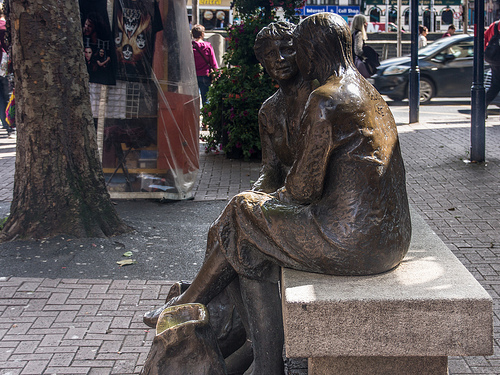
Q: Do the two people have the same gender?
A: No, they are both male and female.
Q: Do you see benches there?
A: Yes, there is a bench.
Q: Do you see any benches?
A: Yes, there is a bench.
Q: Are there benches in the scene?
A: Yes, there is a bench.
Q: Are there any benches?
A: Yes, there is a bench.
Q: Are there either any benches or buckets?
A: Yes, there is a bench.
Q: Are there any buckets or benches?
A: Yes, there is a bench.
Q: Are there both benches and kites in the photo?
A: No, there is a bench but no kites.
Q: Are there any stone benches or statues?
A: Yes, there is a stone bench.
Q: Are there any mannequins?
A: No, there are no mannequins.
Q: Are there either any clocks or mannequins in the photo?
A: No, there are no mannequins or clocks.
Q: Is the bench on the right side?
A: Yes, the bench is on the right of the image.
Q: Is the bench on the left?
A: No, the bench is on the right of the image.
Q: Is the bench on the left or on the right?
A: The bench is on the right of the image.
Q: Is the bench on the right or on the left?
A: The bench is on the right of the image.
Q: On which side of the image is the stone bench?
A: The bench is on the right of the image.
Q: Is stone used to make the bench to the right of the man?
A: Yes, the bench is made of stone.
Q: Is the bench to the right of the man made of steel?
A: No, the bench is made of stone.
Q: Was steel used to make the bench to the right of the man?
A: No, the bench is made of stone.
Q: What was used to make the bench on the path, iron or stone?
A: The bench is made of stone.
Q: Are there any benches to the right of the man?
A: Yes, there is a bench to the right of the man.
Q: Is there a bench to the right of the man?
A: Yes, there is a bench to the right of the man.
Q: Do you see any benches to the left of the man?
A: No, the bench is to the right of the man.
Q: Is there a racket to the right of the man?
A: No, there is a bench to the right of the man.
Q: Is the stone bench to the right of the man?
A: Yes, the bench is to the right of the man.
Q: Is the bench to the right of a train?
A: No, the bench is to the right of the man.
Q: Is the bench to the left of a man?
A: No, the bench is to the right of a man.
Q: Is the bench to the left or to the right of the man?
A: The bench is to the right of the man.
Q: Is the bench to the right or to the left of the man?
A: The bench is to the right of the man.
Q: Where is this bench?
A: The bench is on the path.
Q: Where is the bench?
A: The bench is on the path.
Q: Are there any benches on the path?
A: Yes, there is a bench on the path.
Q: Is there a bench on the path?
A: Yes, there is a bench on the path.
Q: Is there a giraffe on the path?
A: No, there is a bench on the path.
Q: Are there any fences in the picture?
A: No, there are no fences.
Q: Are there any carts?
A: No, there are no carts.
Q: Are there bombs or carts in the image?
A: No, there are no carts or bombs.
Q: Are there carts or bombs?
A: No, there are no carts or bombs.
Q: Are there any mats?
A: No, there are no mats.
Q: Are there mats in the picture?
A: No, there are no mats.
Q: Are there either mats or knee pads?
A: No, there are no mats or knee pads.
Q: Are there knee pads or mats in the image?
A: No, there are no mats or knee pads.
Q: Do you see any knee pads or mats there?
A: No, there are no mats or knee pads.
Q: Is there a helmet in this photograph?
A: No, there are no helmets.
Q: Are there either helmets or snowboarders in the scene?
A: No, there are no helmets or snowboarders.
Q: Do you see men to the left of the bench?
A: Yes, there is a man to the left of the bench.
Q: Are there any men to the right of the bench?
A: No, the man is to the left of the bench.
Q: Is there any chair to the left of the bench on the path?
A: No, there is a man to the left of the bench.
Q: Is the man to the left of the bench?
A: Yes, the man is to the left of the bench.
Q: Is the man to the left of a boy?
A: No, the man is to the left of the bench.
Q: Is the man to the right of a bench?
A: No, the man is to the left of a bench.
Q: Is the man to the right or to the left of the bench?
A: The man is to the left of the bench.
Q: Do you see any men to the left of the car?
A: Yes, there is a man to the left of the car.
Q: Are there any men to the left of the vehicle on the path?
A: Yes, there is a man to the left of the car.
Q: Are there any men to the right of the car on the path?
A: No, the man is to the left of the car.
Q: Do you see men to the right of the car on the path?
A: No, the man is to the left of the car.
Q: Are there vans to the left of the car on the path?
A: No, there is a man to the left of the car.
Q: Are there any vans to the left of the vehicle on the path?
A: No, there is a man to the left of the car.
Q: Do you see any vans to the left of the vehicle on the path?
A: No, there is a man to the left of the car.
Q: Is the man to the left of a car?
A: Yes, the man is to the left of a car.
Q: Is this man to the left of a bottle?
A: No, the man is to the left of a car.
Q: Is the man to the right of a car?
A: No, the man is to the left of a car.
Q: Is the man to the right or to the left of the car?
A: The man is to the left of the car.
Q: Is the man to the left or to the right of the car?
A: The man is to the left of the car.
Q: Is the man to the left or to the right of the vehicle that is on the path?
A: The man is to the left of the car.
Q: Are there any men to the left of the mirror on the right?
A: Yes, there is a man to the left of the mirror.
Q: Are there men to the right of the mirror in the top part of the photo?
A: No, the man is to the left of the mirror.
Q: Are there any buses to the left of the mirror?
A: No, there is a man to the left of the mirror.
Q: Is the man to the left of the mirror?
A: Yes, the man is to the left of the mirror.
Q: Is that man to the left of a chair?
A: No, the man is to the left of the mirror.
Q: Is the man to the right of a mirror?
A: No, the man is to the left of a mirror.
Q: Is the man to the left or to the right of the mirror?
A: The man is to the left of the mirror.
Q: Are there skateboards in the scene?
A: No, there are no skateboards.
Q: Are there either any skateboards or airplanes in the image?
A: No, there are no skateboards or airplanes.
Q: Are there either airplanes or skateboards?
A: No, there are no skateboards or airplanes.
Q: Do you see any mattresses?
A: No, there are no mattresses.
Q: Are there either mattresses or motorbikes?
A: No, there are no mattresses or motorbikes.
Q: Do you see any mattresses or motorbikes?
A: No, there are no mattresses or motorbikes.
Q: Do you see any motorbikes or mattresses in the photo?
A: No, there are no mattresses or motorbikes.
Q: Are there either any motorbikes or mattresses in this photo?
A: No, there are no mattresses or motorbikes.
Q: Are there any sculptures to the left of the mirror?
A: Yes, there is a sculpture to the left of the mirror.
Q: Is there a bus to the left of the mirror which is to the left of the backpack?
A: No, there is a sculpture to the left of the mirror.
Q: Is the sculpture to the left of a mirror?
A: Yes, the sculpture is to the left of a mirror.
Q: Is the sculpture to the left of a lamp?
A: No, the sculpture is to the left of a mirror.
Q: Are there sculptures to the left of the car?
A: Yes, there is a sculpture to the left of the car.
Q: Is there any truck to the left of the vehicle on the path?
A: No, there is a sculpture to the left of the car.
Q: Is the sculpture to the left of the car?
A: Yes, the sculpture is to the left of the car.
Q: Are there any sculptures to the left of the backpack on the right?
A: Yes, there is a sculpture to the left of the backpack.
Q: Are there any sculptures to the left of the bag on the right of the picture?
A: Yes, there is a sculpture to the left of the backpack.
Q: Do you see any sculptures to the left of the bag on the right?
A: Yes, there is a sculpture to the left of the backpack.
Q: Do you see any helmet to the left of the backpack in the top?
A: No, there is a sculpture to the left of the backpack.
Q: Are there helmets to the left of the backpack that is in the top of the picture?
A: No, there is a sculpture to the left of the backpack.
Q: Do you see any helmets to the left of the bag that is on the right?
A: No, there is a sculpture to the left of the backpack.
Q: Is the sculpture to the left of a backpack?
A: Yes, the sculpture is to the left of a backpack.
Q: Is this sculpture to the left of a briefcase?
A: No, the sculpture is to the left of a backpack.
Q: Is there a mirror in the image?
A: Yes, there is a mirror.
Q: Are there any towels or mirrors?
A: Yes, there is a mirror.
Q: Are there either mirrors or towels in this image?
A: Yes, there is a mirror.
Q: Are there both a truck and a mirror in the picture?
A: No, there is a mirror but no trucks.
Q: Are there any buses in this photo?
A: No, there are no buses.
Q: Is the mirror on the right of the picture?
A: Yes, the mirror is on the right of the image.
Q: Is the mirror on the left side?
A: No, the mirror is on the right of the image.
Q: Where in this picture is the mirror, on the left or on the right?
A: The mirror is on the right of the image.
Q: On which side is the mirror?
A: The mirror is on the right of the image.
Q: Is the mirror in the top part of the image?
A: Yes, the mirror is in the top of the image.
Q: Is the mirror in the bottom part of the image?
A: No, the mirror is in the top of the image.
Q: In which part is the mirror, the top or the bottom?
A: The mirror is in the top of the image.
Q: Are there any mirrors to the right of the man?
A: Yes, there is a mirror to the right of the man.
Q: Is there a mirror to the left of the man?
A: No, the mirror is to the right of the man.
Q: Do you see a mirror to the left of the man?
A: No, the mirror is to the right of the man.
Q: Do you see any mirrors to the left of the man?
A: No, the mirror is to the right of the man.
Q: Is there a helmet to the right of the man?
A: No, there is a mirror to the right of the man.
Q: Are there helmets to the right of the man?
A: No, there is a mirror to the right of the man.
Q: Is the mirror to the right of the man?
A: Yes, the mirror is to the right of the man.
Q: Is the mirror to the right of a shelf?
A: No, the mirror is to the right of the man.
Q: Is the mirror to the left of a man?
A: No, the mirror is to the right of a man.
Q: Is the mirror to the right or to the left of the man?
A: The mirror is to the right of the man.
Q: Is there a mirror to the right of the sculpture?
A: Yes, there is a mirror to the right of the sculpture.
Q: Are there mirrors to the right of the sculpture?
A: Yes, there is a mirror to the right of the sculpture.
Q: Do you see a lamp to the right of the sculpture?
A: No, there is a mirror to the right of the sculpture.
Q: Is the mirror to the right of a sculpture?
A: Yes, the mirror is to the right of a sculpture.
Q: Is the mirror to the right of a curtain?
A: No, the mirror is to the right of a sculpture.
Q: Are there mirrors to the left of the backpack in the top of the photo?
A: Yes, there is a mirror to the left of the backpack.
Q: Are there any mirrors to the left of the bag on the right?
A: Yes, there is a mirror to the left of the backpack.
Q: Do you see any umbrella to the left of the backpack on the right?
A: No, there is a mirror to the left of the backpack.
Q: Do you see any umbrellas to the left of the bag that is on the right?
A: No, there is a mirror to the left of the backpack.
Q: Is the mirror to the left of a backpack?
A: Yes, the mirror is to the left of a backpack.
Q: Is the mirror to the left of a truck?
A: No, the mirror is to the left of a backpack.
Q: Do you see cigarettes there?
A: No, there are no cigarettes.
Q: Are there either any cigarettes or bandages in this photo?
A: No, there are no cigarettes or bandages.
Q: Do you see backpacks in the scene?
A: Yes, there is a backpack.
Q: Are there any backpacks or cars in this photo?
A: Yes, there is a backpack.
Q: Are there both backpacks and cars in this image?
A: Yes, there are both a backpack and a car.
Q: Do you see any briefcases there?
A: No, there are no briefcases.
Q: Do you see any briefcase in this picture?
A: No, there are no briefcases.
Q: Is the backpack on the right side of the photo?
A: Yes, the backpack is on the right of the image.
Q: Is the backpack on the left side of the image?
A: No, the backpack is on the right of the image.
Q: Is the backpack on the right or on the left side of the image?
A: The backpack is on the right of the image.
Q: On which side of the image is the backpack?
A: The backpack is on the right of the image.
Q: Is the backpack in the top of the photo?
A: Yes, the backpack is in the top of the image.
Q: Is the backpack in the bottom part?
A: No, the backpack is in the top of the image.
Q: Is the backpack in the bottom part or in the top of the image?
A: The backpack is in the top of the image.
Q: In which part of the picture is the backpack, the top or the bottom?
A: The backpack is in the top of the image.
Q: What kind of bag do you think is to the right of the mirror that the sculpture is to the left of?
A: The bag is a backpack.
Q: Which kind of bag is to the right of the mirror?
A: The bag is a backpack.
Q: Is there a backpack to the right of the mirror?
A: Yes, there is a backpack to the right of the mirror.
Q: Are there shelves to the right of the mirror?
A: No, there is a backpack to the right of the mirror.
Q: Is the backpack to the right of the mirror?
A: Yes, the backpack is to the right of the mirror.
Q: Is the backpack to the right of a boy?
A: No, the backpack is to the right of the mirror.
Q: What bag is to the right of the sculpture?
A: The bag is a backpack.